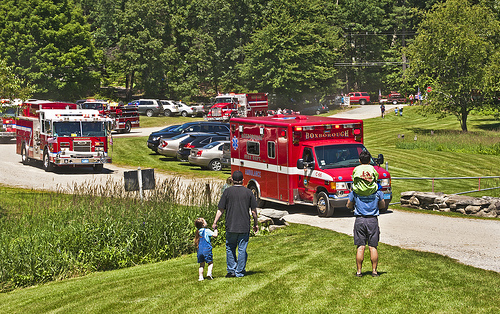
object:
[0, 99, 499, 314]
grass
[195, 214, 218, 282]
child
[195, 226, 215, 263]
overalls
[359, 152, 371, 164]
hair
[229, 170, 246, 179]
hat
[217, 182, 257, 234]
pullover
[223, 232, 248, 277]
jeans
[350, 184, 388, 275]
man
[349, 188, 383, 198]
shoulders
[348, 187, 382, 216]
pullover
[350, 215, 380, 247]
shorts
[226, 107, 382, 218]
vehicle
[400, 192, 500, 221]
wall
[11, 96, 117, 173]
fire truck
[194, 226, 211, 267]
outfit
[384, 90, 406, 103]
truck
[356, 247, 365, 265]
calves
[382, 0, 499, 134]
tree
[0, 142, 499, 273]
road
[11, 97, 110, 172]
truck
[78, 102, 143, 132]
fire truck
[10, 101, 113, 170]
fire rescue truck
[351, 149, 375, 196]
girl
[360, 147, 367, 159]
ponytail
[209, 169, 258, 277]
spectators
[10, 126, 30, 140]
stripe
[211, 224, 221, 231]
hand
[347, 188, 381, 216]
tee shirt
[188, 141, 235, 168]
car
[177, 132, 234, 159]
car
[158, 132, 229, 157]
car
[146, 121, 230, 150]
car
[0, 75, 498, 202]
middle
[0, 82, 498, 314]
field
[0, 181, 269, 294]
weeds